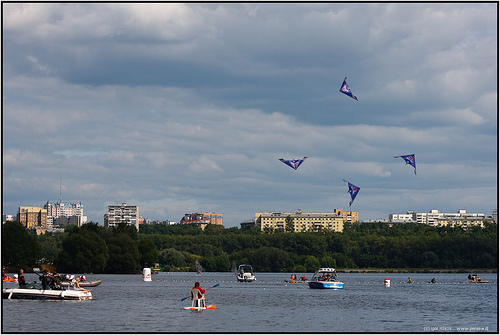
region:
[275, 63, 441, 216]
Kites flying in the sky.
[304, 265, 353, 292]
Blue boat in the water.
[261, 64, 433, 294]
Blue kites flying above blue boat.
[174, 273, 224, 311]
Person floating in lawn chair with oar.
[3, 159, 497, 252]
Building in a city behind trees.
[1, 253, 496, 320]
Boaters floating on the water.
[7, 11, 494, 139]
Dark clouds covering the sky.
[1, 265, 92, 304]
Boat floating with two people on board.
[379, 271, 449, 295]
Orange buoy in water next to swimmers.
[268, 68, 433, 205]
Triangle kites with red centers flying in sky.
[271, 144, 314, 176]
the kite is in the sky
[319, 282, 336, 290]
the boat is blue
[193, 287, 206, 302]
the person is sitting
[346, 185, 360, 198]
the kite is blue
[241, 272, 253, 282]
the boat is white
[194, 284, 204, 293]
the shirt is red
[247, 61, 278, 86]
the clouds are blue gray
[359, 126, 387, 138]
the cloud is white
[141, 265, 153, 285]
the barrier is white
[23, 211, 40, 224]
the building is brown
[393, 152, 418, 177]
blue kite flying in air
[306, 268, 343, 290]
blue and white boat on water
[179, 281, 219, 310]
person on chair in water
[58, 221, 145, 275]
green trees by water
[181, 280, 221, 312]
person holding oar on water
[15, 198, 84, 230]
buildings in background behind trees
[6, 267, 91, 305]
people on white watercraft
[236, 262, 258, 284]
white motorboat on water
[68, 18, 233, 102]
gray clouds in sky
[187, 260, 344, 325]
people spending time on water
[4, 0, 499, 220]
grey cloudy skies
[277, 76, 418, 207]
four kites flying in sync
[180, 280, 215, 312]
a man riding a raft while sitting in a chair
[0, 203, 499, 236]
hotels and condos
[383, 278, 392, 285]
orange and white bouy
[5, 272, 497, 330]
water that's not too choppy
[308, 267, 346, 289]
blue and white boat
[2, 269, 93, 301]
black and white raft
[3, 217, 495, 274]
trees on the lake shore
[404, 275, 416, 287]
a person swimming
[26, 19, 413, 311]
this is a river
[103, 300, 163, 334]
the water is blue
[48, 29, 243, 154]
the sky is very cloudy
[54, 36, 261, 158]
the skys is gray and white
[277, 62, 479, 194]
this is a bunch of kites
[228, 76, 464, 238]
the kites are purple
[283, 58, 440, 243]
the kites are flying on the wind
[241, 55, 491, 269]
there are four kites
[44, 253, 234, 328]
these are boats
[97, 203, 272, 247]
the water front is green